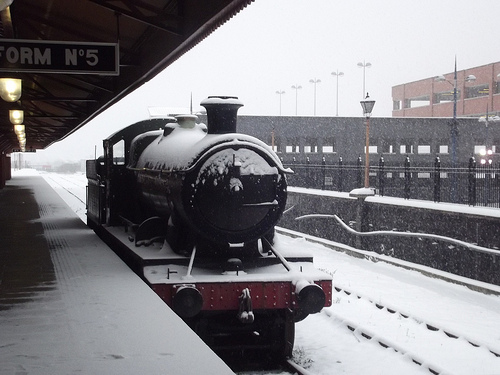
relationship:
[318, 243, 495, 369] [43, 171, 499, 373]
snow on tracks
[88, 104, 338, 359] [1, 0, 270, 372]
train at station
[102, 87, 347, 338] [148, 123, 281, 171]
black train covered in snow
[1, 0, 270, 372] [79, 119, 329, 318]
station for train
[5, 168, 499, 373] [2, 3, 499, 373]
snow on station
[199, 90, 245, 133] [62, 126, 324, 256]
stack of train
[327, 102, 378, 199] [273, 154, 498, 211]
pole on fence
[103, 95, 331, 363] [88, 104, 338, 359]
engine of train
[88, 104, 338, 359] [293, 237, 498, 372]
train in snow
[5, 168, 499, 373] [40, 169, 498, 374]
snow on ground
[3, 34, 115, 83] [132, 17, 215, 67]
sign under awning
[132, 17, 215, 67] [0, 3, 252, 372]
awning on train station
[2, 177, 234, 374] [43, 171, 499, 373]
sidewalk next to tracks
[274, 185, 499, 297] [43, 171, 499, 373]
fence next to tracks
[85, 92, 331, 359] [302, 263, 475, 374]
train on train tracks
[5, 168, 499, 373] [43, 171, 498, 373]
snow on train track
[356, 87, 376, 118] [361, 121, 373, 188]
lamp on post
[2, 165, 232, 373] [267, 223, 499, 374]
walkway next to train tracks